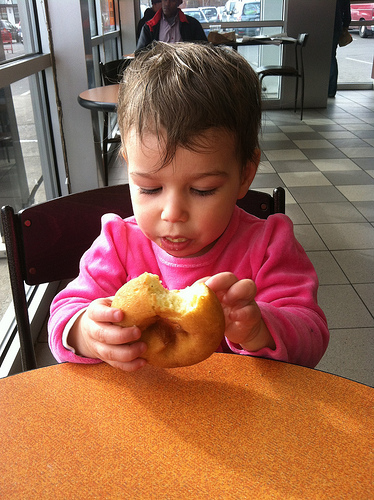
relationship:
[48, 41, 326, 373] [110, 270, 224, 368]
child eating donut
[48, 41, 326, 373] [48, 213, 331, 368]
child wearing shirt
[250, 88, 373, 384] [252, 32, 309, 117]
floor under chair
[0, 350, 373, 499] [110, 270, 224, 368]
table under donut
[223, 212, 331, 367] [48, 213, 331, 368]
sleeve of shirt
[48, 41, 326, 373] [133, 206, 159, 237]
child has cheek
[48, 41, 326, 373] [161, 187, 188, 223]
child has nose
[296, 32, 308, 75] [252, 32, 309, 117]
back of chair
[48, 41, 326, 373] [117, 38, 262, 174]
child has hair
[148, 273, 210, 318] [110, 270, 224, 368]
bite in donut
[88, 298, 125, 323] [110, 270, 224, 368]
finger on donut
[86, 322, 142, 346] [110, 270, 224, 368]
finger on donut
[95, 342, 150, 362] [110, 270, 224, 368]
finger on donut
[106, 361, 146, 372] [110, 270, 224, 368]
finger on donut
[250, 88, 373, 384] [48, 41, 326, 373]
floor behind child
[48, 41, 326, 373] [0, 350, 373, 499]
child at table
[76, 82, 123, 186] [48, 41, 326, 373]
table behind child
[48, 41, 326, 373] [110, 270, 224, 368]
child holding donut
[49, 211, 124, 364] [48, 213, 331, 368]
sleeve of shirt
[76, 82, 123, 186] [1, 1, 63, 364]
table near window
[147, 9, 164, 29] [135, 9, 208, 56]
collar on jacket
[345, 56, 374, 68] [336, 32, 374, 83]
line on street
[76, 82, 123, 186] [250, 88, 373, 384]
table on floor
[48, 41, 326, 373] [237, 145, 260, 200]
child has ear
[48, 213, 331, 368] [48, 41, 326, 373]
shirt on child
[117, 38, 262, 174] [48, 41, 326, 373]
hair on child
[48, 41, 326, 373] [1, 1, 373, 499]
child in restaurant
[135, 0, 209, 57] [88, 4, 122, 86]
man looking out window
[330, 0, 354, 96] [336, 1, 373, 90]
person walking out door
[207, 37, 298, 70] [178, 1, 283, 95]
table near window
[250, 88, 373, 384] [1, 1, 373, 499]
floor of restaurant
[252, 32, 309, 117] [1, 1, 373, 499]
chair in restaurant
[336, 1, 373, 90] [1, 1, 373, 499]
door of restaurant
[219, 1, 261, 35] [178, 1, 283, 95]
vehicle outside window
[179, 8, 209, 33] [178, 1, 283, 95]
vehicle outside window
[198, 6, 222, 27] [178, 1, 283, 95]
vehicle outside window